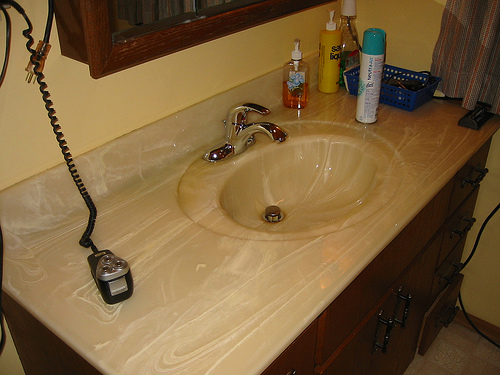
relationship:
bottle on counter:
[279, 37, 310, 110] [2, 46, 499, 372]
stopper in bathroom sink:
[253, 187, 323, 259] [173, 119, 406, 242]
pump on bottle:
[290, 37, 303, 60] [281, 37, 309, 107]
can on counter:
[354, 27, 386, 123] [2, 46, 499, 372]